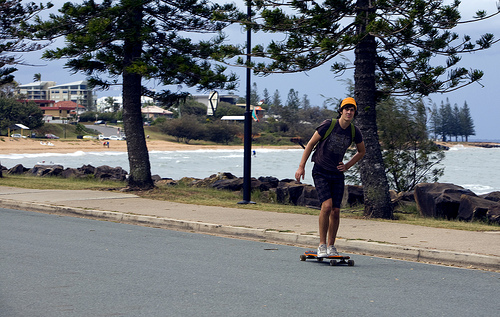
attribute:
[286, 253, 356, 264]
skateboard — orange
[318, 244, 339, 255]
shoes — white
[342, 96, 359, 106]
hat — orange, yellow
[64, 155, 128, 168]
water — blue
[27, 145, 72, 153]
beach — sandy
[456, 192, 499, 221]
rock — large, grey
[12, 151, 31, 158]
wave — whitecapped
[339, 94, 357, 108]
cap — yellow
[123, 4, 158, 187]
tree — tall, pine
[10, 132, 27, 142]
car — parked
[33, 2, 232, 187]
tree — pine, evergreen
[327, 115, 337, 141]
strap — green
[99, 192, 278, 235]
sidewalk — concrete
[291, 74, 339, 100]
sky — blue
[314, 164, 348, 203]
shorts — checkered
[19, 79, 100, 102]
houses — many